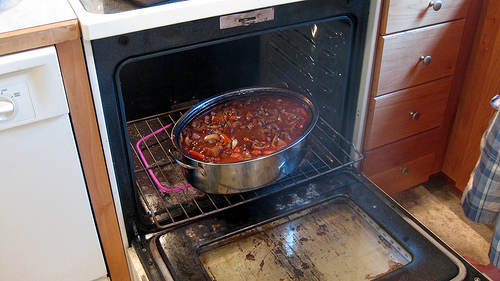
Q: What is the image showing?
A: It is showing a kitchen.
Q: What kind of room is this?
A: It is a kitchen.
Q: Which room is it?
A: It is a kitchen.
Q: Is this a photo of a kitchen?
A: Yes, it is showing a kitchen.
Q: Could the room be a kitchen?
A: Yes, it is a kitchen.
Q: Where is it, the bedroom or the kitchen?
A: It is the kitchen.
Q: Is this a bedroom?
A: No, it is a kitchen.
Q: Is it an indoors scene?
A: Yes, it is indoors.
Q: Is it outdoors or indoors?
A: It is indoors.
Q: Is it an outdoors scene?
A: No, it is indoors.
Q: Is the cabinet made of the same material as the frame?
A: Yes, both the cabinet and the frame are made of wood.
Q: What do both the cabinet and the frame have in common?
A: The material, both the cabinet and the frame are wooden.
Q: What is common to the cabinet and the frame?
A: The material, both the cabinet and the frame are wooden.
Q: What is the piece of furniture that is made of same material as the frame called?
A: The piece of furniture is a cabinet.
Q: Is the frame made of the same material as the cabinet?
A: Yes, both the frame and the cabinet are made of wood.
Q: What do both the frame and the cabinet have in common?
A: The material, both the frame and the cabinet are wooden.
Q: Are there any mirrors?
A: No, there are no mirrors.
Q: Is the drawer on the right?
A: Yes, the drawer is on the right of the image.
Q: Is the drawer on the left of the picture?
A: No, the drawer is on the right of the image.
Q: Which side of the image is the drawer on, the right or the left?
A: The drawer is on the right of the image.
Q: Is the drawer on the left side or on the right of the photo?
A: The drawer is on the right of the image.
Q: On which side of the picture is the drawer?
A: The drawer is on the right of the image.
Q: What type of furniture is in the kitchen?
A: The piece of furniture is a drawer.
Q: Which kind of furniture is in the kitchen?
A: The piece of furniture is a drawer.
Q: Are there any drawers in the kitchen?
A: Yes, there is a drawer in the kitchen.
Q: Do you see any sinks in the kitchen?
A: No, there is a drawer in the kitchen.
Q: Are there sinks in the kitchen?
A: No, there is a drawer in the kitchen.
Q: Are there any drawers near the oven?
A: Yes, there is a drawer near the oven.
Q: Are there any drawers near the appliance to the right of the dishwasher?
A: Yes, there is a drawer near the oven.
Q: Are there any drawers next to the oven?
A: Yes, there is a drawer next to the oven.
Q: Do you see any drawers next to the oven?
A: Yes, there is a drawer next to the oven.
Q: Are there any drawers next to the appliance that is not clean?
A: Yes, there is a drawer next to the oven.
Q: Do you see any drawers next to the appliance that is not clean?
A: Yes, there is a drawer next to the oven.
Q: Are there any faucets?
A: No, there are no faucets.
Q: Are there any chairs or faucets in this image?
A: No, there are no faucets or chairs.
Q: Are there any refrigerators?
A: No, there are no refrigerators.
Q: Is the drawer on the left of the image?
A: No, the drawer is on the right of the image.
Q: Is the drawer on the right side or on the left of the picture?
A: The drawer is on the right of the image.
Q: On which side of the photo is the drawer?
A: The drawer is on the right of the image.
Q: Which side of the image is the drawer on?
A: The drawer is on the right of the image.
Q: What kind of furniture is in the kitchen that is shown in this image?
A: The piece of furniture is a drawer.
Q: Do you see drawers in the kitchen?
A: Yes, there is a drawer in the kitchen.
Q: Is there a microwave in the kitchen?
A: No, there is a drawer in the kitchen.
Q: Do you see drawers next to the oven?
A: Yes, there is a drawer next to the oven.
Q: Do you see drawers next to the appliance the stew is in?
A: Yes, there is a drawer next to the oven.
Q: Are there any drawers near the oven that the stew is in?
A: Yes, there is a drawer near the oven.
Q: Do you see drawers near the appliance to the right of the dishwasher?
A: Yes, there is a drawer near the oven.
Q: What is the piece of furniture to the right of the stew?
A: The piece of furniture is a drawer.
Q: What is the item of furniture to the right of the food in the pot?
A: The piece of furniture is a drawer.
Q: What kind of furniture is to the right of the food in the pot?
A: The piece of furniture is a drawer.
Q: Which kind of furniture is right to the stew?
A: The piece of furniture is a drawer.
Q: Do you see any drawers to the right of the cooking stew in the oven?
A: Yes, there is a drawer to the right of the stew.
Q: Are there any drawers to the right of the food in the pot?
A: Yes, there is a drawer to the right of the stew.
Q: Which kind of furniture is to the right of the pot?
A: The piece of furniture is a drawer.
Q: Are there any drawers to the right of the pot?
A: Yes, there is a drawer to the right of the pot.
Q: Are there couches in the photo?
A: No, there are no couches.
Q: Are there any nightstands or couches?
A: No, there are no couches or nightstands.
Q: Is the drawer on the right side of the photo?
A: Yes, the drawer is on the right of the image.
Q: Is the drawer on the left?
A: No, the drawer is on the right of the image.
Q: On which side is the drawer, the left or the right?
A: The drawer is on the right of the image.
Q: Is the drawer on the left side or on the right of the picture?
A: The drawer is on the right of the image.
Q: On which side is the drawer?
A: The drawer is on the right of the image.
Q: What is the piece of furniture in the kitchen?
A: The piece of furniture is a drawer.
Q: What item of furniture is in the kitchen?
A: The piece of furniture is a drawer.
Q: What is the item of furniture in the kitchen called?
A: The piece of furniture is a drawer.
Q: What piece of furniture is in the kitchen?
A: The piece of furniture is a drawer.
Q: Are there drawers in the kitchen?
A: Yes, there is a drawer in the kitchen.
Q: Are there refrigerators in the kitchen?
A: No, there is a drawer in the kitchen.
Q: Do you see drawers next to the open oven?
A: Yes, there is a drawer next to the oven.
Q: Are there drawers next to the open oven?
A: Yes, there is a drawer next to the oven.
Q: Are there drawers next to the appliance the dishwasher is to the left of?
A: Yes, there is a drawer next to the oven.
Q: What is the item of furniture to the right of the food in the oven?
A: The piece of furniture is a drawer.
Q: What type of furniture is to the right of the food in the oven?
A: The piece of furniture is a drawer.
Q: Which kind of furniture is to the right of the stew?
A: The piece of furniture is a drawer.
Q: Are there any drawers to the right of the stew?
A: Yes, there is a drawer to the right of the stew.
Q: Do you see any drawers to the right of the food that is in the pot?
A: Yes, there is a drawer to the right of the stew.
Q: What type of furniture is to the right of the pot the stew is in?
A: The piece of furniture is a drawer.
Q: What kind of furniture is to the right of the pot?
A: The piece of furniture is a drawer.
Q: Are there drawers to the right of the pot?
A: Yes, there is a drawer to the right of the pot.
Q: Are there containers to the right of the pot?
A: No, there is a drawer to the right of the pot.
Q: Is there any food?
A: Yes, there is food.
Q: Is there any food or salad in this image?
A: Yes, there is food.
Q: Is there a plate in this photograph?
A: No, there are no plates.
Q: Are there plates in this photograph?
A: No, there are no plates.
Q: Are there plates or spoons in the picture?
A: No, there are no plates or spoons.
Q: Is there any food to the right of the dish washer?
A: Yes, there is food to the right of the dish washer.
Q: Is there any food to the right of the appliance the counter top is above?
A: Yes, there is food to the right of the dish washer.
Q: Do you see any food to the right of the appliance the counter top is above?
A: Yes, there is food to the right of the dish washer.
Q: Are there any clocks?
A: No, there are no clocks.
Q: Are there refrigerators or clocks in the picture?
A: No, there are no clocks or refrigerators.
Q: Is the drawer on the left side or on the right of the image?
A: The drawer is on the right of the image.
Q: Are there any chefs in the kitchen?
A: No, there is a drawer in the kitchen.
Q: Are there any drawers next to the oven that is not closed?
A: Yes, there is a drawer next to the oven.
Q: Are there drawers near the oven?
A: Yes, there is a drawer near the oven.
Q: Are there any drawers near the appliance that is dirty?
A: Yes, there is a drawer near the oven.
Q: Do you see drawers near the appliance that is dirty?
A: Yes, there is a drawer near the oven.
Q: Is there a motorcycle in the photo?
A: No, there are no motorcycles.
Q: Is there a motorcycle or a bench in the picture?
A: No, there are no motorcycles or benches.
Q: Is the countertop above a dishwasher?
A: Yes, the countertop is above a dishwasher.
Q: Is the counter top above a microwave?
A: No, the counter top is above a dishwasher.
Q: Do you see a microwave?
A: No, there are no microwaves.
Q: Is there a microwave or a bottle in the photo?
A: No, there are no microwaves or bottles.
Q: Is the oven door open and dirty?
A: Yes, the oven door is open and dirty.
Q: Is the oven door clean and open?
A: No, the oven door is open but dirty.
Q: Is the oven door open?
A: Yes, the oven door is open.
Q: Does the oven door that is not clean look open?
A: Yes, the oven door is open.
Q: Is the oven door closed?
A: No, the oven door is open.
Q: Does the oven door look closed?
A: No, the oven door is open.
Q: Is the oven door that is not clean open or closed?
A: The oven door is open.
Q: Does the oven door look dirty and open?
A: Yes, the oven door is dirty and open.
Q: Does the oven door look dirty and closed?
A: No, the oven door is dirty but open.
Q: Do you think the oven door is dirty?
A: Yes, the oven door is dirty.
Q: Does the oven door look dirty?
A: Yes, the oven door is dirty.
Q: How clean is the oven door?
A: The oven door is dirty.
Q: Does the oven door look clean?
A: No, the oven door is dirty.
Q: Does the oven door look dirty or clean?
A: The oven door is dirty.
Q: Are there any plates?
A: No, there are no plates.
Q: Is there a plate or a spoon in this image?
A: No, there are no plates or spoons.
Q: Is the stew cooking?
A: Yes, the stew is cooking.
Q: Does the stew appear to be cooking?
A: Yes, the stew is cooking.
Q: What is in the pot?
A: The stew is in the pot.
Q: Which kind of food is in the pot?
A: The food is stew.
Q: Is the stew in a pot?
A: Yes, the stew is in a pot.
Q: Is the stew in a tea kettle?
A: No, the stew is in a pot.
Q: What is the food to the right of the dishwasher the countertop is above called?
A: The food is stew.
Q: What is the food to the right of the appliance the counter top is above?
A: The food is stew.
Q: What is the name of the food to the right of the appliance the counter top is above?
A: The food is stew.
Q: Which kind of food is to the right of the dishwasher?
A: The food is stew.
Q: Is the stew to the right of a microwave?
A: No, the stew is to the right of a dishwasher.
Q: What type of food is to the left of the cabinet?
A: The food is stew.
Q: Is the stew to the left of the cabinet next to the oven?
A: Yes, the stew is to the left of the cabinet.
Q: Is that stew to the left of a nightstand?
A: No, the stew is to the left of the cabinet.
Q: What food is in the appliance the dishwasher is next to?
A: The food is stew.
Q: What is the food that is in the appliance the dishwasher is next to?
A: The food is stew.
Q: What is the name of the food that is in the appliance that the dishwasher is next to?
A: The food is stew.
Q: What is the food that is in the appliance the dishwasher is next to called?
A: The food is stew.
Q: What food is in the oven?
A: The food is stew.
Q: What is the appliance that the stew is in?
A: The appliance is an oven.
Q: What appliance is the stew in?
A: The stew is in the oven.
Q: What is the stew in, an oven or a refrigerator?
A: The stew is in an oven.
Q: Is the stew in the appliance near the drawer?
A: Yes, the stew is in the oven.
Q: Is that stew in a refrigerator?
A: No, the stew is in the oven.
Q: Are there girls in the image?
A: No, there are no girls.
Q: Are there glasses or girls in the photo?
A: No, there are no girls or glasses.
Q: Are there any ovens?
A: Yes, there is an oven.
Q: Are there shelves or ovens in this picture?
A: Yes, there is an oven.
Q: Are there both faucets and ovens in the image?
A: No, there is an oven but no faucets.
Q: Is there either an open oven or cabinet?
A: Yes, there is an open oven.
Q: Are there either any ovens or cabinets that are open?
A: Yes, the oven is open.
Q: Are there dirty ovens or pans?
A: Yes, there is a dirty oven.